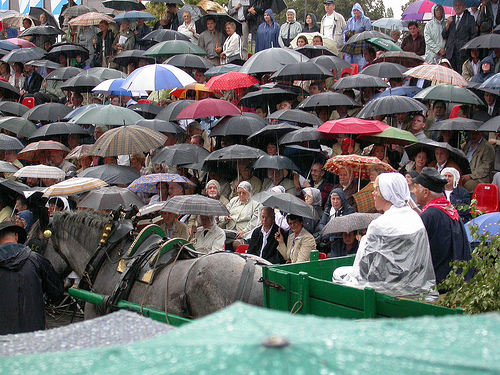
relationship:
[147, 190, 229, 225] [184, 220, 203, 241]
umbrella in hand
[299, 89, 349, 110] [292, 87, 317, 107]
umbrella in a hand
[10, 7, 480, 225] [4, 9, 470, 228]
group of people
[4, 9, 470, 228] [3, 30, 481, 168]
people with umbrellas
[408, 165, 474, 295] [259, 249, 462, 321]
man in a trailer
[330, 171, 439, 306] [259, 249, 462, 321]
woman in a trailer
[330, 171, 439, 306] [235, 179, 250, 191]
woman with a hat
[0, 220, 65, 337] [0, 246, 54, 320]
man in a jacket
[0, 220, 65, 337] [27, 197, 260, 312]
man next to horse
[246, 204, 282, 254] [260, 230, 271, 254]
man in a shirt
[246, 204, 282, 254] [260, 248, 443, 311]
man looking at buggy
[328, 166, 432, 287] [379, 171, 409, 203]
woman with a hat on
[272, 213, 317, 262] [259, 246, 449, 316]
people sitting in trailer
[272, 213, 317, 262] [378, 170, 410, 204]
people wearing cap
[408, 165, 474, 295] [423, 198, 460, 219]
man wearing neckerchief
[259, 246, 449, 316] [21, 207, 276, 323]
trailer behind horse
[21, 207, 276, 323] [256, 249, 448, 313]
horse pulling trailer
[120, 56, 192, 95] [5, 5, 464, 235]
umbrella in crowd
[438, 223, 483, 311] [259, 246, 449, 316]
plant in trailer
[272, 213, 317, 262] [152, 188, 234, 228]
people with umbrella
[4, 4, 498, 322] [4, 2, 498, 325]
crowd standing under umbrellas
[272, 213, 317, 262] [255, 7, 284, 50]
people wearing jacket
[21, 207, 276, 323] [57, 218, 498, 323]
horse pulling a wagon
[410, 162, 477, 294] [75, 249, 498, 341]
man riding in wagon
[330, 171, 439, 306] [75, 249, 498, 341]
woman riding in wagon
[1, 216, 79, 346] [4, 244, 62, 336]
man in clothes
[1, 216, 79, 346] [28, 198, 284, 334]
man leading horse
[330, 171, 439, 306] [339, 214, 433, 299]
woman in clothes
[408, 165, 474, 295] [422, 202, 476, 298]
man in clothing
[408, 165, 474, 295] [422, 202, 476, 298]
man wearing clothing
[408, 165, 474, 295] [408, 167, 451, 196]
man wearing hat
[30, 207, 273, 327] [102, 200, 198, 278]
horse with saddle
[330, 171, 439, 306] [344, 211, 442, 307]
woman in covering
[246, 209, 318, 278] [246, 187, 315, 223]
couple sharing an umbrella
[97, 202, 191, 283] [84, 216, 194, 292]
saddle with embellishments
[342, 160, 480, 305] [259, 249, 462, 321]
couple in trailer